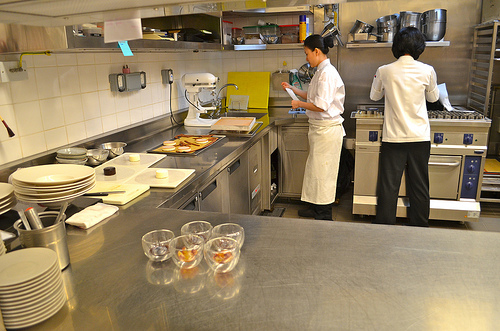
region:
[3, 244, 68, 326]
a stack of plates on a counter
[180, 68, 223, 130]
a mixer on a counter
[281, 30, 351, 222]
a woman wearing a white apron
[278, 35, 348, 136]
a woman holding a piece of paper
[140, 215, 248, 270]
five little glass bowl on a counter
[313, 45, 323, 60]
an ear of a woman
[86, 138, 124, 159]
two stainless steel bowls on a counter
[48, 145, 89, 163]
a stack of bowl on a counter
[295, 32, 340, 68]
the head of a woman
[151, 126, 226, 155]
some food on a tray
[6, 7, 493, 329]
Kitchen owned by a restaurant.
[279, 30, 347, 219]
Lady chef preparing meals.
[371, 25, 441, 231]
Chef's assistant helping with cleaning.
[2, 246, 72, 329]
A stack of clean plates.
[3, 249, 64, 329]
White and round plates.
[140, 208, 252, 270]
Small glass containers containing various sauces.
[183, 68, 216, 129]
White KitchenAid blender.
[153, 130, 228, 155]
Pancakes on rectangle pan.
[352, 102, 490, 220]
Professional oven with blue knobs.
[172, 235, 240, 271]
Pancake syrup in small glass containers.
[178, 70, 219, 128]
A white stand mixer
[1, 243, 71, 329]
A stack of white plates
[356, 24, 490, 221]
A person standing in front of a stove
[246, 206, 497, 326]
A stainless steel counter top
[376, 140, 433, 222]
A person wearing black pants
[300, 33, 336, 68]
A woman with black hair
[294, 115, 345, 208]
An apron tied around a woman's waist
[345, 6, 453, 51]
Bowls on a shelf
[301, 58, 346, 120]
A woman wearing a white shirt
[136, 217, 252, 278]
Small glass bowls on a counter top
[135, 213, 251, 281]
five small glass bowls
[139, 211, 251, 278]
small glass bowls on stainless steel counter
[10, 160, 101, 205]
small stack of white plates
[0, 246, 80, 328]
large stack of white plates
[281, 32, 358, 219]
chef in kitchen wearing apron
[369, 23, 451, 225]
chef in black pants cooking at stove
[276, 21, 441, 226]
two chefs cooking in restaurant kitchen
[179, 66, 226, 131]
white stand mixer on kitchen counter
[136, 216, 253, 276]
small clear glass bowls on kitchen counter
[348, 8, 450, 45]
shelf with stacked metal bowls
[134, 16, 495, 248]
two cooks in a kitchen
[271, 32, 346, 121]
a woman looking at a piece of paper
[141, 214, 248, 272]
five shiny glass bowls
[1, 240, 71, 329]
a stack of white plates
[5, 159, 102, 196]
a stack of white plates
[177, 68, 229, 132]
a white mixer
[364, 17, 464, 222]
a woman wearing white and black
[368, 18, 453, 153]
a woman wearing a white jacket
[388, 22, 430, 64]
the head of a woman